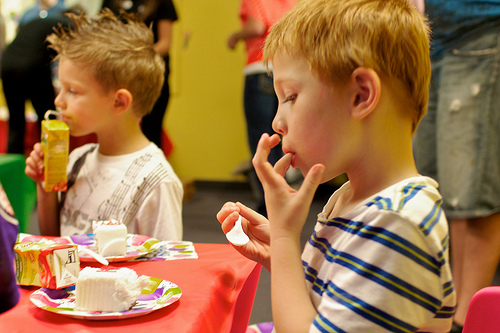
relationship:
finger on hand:
[256, 131, 278, 186] [250, 121, 324, 240]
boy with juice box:
[24, 9, 195, 252] [27, 101, 77, 194]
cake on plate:
[92, 219, 126, 256] [62, 234, 161, 261]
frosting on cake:
[93, 220, 127, 255] [92, 219, 126, 256]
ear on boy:
[109, 86, 132, 118] [24, 9, 184, 242]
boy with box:
[24, 9, 184, 242] [41, 106, 139, 186]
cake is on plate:
[92, 219, 126, 256] [28, 277, 142, 322]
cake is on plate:
[70, 260, 142, 315] [26, 261, 185, 322]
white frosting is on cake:
[71, 266, 136, 311] [74, 267, 151, 313]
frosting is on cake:
[93, 220, 127, 255] [88, 211, 133, 259]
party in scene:
[28, 15, 458, 320] [2, 4, 496, 325]